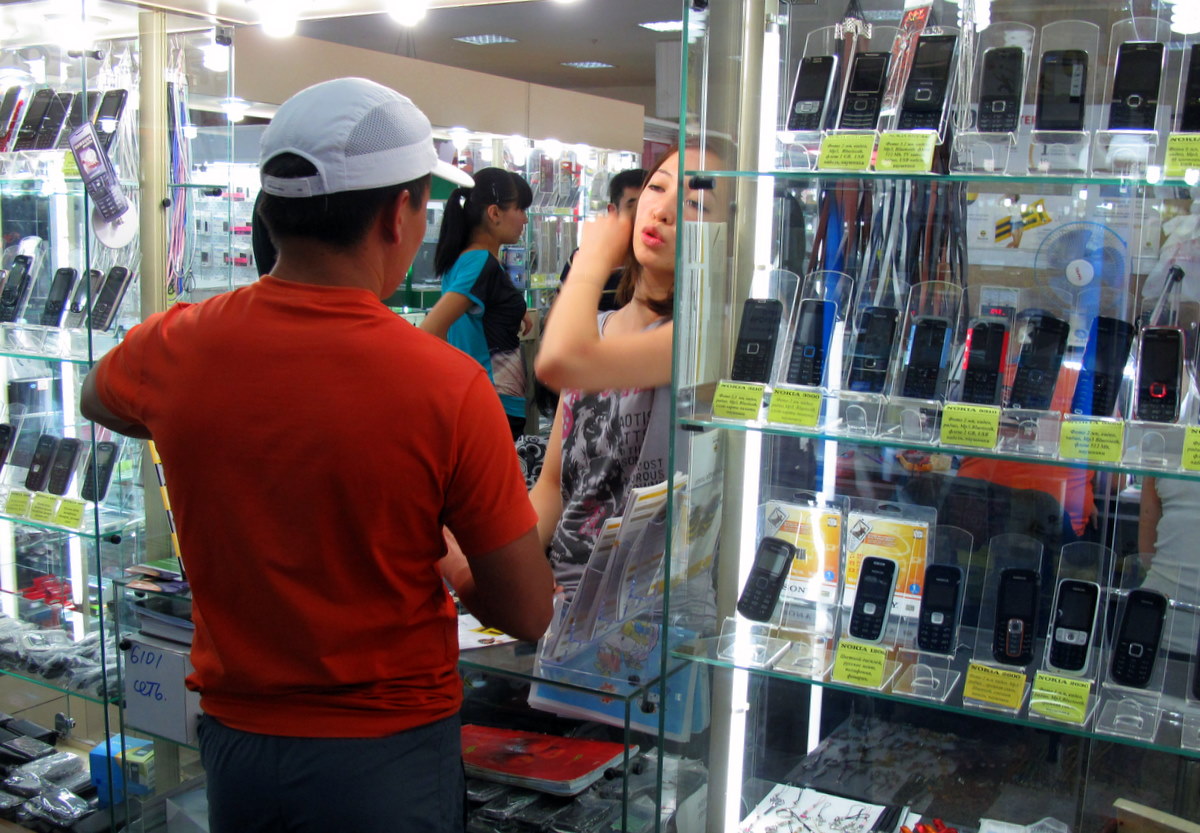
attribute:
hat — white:
[249, 69, 473, 204]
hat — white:
[256, 76, 476, 202]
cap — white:
[264, 69, 475, 197]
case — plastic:
[648, 15, 1162, 811]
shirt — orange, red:
[88, 259, 533, 730]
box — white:
[118, 630, 203, 745]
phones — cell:
[775, 29, 1193, 829]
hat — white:
[254, 73, 487, 219]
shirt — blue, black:
[433, 245, 531, 386]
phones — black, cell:
[712, 500, 1198, 715]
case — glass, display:
[670, 1, 1193, 827]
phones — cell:
[734, 291, 1198, 428]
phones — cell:
[786, 23, 1196, 138]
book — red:
[457, 705, 640, 811]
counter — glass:
[430, 631, 704, 827]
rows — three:
[727, 3, 1198, 742]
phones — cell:
[727, 20, 1196, 709]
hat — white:
[232, 77, 498, 203]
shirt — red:
[110, 276, 535, 775]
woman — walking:
[430, 156, 543, 409]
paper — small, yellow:
[699, 365, 757, 445]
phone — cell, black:
[725, 278, 781, 402]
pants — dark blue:
[195, 703, 480, 827]